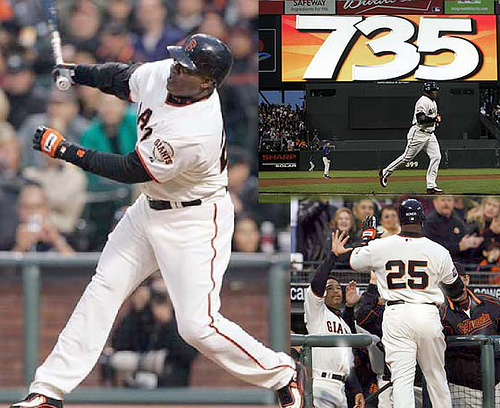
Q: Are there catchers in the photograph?
A: No, there are no catchers.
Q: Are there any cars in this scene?
A: No, there are no cars.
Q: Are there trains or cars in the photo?
A: No, there are no cars or trains.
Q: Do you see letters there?
A: Yes, there are letters.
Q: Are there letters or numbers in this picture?
A: Yes, there are letters.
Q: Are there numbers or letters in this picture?
A: Yes, there are letters.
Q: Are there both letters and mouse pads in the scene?
A: No, there are letters but no mouse pads.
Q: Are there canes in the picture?
A: No, there are no canes.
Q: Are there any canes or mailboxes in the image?
A: No, there are no canes or mailboxes.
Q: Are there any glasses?
A: No, there are no glasses.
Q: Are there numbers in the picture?
A: Yes, there are numbers.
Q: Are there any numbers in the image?
A: Yes, there are numbers.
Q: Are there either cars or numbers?
A: Yes, there are numbers.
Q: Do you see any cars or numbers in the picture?
A: Yes, there are numbers.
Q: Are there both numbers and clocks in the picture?
A: No, there are numbers but no clocks.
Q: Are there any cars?
A: No, there are no cars.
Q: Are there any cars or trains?
A: No, there are no cars or trains.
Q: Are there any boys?
A: No, there are no boys.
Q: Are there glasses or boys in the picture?
A: No, there are no boys or glasses.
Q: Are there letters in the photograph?
A: Yes, there are letters.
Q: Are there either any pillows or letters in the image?
A: Yes, there are letters.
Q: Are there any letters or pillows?
A: Yes, there are letters.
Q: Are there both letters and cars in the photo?
A: No, there are letters but no cars.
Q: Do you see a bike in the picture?
A: No, there are no bikes.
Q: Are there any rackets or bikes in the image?
A: No, there are no bikes or rackets.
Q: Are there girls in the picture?
A: No, there are no girls.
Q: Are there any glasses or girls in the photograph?
A: No, there are no girls or glasses.